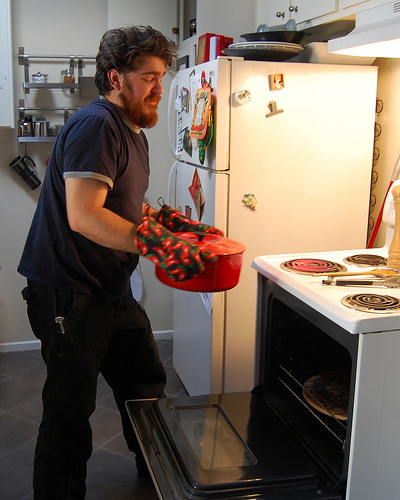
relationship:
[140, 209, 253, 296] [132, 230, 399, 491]
pot near oven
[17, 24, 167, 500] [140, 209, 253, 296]
man with a pot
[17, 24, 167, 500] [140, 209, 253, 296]
man holding pot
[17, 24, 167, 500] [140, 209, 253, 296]
man handling a pot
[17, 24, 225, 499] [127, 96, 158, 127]
man with a beard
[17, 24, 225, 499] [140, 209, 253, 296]
man carrying a pot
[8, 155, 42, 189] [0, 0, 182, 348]
bottle hanging on wall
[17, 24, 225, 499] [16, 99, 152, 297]
man wearing a blue shirt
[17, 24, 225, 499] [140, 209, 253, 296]
man holding pot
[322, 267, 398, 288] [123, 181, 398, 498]
utensils on top of stove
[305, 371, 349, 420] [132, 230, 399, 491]
pizza in oven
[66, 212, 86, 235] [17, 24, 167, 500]
elbow of man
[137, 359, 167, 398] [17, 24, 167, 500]
knee area of man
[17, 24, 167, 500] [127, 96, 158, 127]
man with a beard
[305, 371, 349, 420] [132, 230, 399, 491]
pizza cooking in oven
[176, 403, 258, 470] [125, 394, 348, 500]
window to oven door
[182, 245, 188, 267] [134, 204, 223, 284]
red pepper on gloves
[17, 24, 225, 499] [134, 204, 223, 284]
man wearing gloves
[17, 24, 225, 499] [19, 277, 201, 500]
man wearing black pants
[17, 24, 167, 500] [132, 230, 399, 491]
man near oven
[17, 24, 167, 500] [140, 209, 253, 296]
man has pot